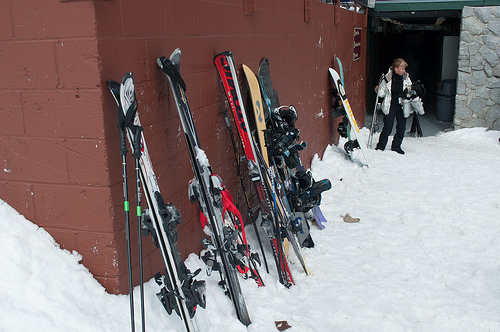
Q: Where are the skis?
A: Resting against the building.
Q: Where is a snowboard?
A: At the far end of the building.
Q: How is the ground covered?
A: Covered in snow.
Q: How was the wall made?
A: Made with cinder blocks.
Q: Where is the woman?
A: In the opening between two walls.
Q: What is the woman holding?
A: Her skis.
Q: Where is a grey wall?
A: Far right hand corner.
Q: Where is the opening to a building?
A: Between red and grey walls.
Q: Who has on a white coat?
A: The woman.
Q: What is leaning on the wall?
A: Skis.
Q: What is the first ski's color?
A: White.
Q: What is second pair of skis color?
A: Black or grey.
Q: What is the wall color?
A: Red.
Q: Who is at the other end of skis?
A: A woman.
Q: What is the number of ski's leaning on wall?
A: Six.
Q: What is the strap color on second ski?
A: Red.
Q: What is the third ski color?
A: Red and black.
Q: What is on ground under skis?
A: Snow.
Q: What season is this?
A: Winter.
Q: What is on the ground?
A: Snow.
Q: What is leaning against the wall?
A: Skis.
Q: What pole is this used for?
A: Skiing.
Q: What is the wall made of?
A: Brick.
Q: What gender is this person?
A: Female.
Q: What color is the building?
A: Brown.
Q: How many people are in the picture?
A: 1.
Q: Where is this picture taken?
A: At a ski resort.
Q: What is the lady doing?
A: Preparing to ski.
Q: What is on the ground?
A: Snow.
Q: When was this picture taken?
A: Winter.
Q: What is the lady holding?
A: Ski sticks.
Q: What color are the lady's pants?
A: Black.